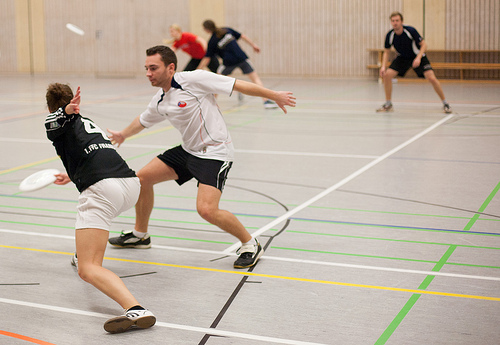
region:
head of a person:
[136, 45, 181, 97]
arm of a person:
[191, 81, 288, 113]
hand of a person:
[272, 90, 306, 122]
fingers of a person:
[288, 90, 298, 111]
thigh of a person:
[198, 165, 220, 207]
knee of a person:
[189, 200, 213, 225]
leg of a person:
[204, 204, 251, 240]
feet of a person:
[230, 243, 277, 278]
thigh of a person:
[77, 197, 125, 255]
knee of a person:
[74, 265, 84, 281]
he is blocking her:
[46, 63, 227, 149]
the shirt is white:
[173, 106, 203, 128]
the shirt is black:
[66, 134, 90, 162]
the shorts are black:
[396, 57, 403, 69]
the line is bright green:
[392, 232, 409, 246]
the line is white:
[331, 258, 350, 270]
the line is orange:
[13, 326, 25, 343]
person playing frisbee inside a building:
[12, 75, 168, 343]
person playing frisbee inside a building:
[107, 43, 299, 273]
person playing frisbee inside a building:
[363, 8, 456, 119]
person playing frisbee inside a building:
[192, 12, 267, 89]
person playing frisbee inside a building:
[165, 17, 206, 74]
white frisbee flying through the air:
[62, 18, 84, 38]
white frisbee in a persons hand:
[17, 160, 64, 197]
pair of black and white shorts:
[155, 140, 237, 191]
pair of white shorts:
[71, 171, 144, 238]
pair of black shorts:
[386, 53, 436, 81]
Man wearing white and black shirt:
[103, 45, 298, 269]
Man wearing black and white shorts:
[108, 43, 295, 271]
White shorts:
[71, 173, 141, 230]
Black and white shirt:
[43, 105, 138, 192]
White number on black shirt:
[80, 116, 111, 141]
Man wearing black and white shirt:
[375, 11, 452, 115]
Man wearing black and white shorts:
[375, 11, 452, 113]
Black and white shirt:
[383, 24, 427, 58]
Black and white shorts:
[387, 50, 436, 79]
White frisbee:
[19, 166, 59, 192]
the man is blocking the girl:
[40, 46, 270, 284]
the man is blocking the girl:
[11, 38, 245, 260]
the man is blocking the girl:
[31, 45, 291, 247]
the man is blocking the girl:
[15, 38, 275, 243]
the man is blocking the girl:
[13, 42, 279, 257]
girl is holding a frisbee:
[24, 62, 136, 243]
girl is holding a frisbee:
[12, 66, 107, 219]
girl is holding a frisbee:
[10, 70, 112, 202]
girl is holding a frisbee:
[0, 60, 127, 202]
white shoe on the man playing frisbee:
[99, 309, 156, 331]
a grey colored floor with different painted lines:
[178, 260, 253, 341]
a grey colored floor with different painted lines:
[0, 282, 51, 342]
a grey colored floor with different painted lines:
[183, 300, 228, 342]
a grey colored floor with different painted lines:
[376, 272, 437, 312]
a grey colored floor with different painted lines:
[404, 256, 454, 291]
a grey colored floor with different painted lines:
[438, 213, 494, 272]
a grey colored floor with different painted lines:
[306, 166, 362, 208]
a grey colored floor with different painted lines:
[262, 196, 314, 235]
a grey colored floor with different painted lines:
[0, 155, 37, 202]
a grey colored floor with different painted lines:
[413, 95, 490, 153]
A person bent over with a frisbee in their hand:
[17, 91, 187, 343]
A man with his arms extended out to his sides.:
[109, 32, 296, 284]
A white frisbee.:
[14, 167, 61, 192]